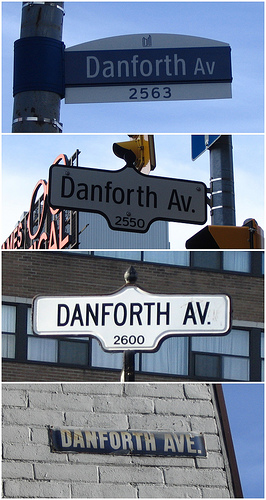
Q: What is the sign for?
A: Street.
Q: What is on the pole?
A: Sign.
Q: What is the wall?
A: Brick.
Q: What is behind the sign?
A: Building.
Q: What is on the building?
A: Windows.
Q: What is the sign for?
A: Danforth av.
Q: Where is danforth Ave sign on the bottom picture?
A: A brick building.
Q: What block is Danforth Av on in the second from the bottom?
A: The 2600 block.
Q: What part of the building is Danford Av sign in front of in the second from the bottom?
A: The windows.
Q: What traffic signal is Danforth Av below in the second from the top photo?
A: A traffic light.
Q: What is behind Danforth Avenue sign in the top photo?
A: The sky.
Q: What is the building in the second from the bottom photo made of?
A: Brick.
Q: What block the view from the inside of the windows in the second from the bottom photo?
A: The white blinds.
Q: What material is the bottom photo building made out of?
A: Brick.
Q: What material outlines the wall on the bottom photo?
A: Metal.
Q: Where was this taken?
A: Danforth Ave.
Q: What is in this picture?
A: Signs.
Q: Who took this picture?
A: A photographer.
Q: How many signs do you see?
A: Four.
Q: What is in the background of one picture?
A: Another sign.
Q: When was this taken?
A: Daytime.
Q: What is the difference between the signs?
A: Different parts of the street.